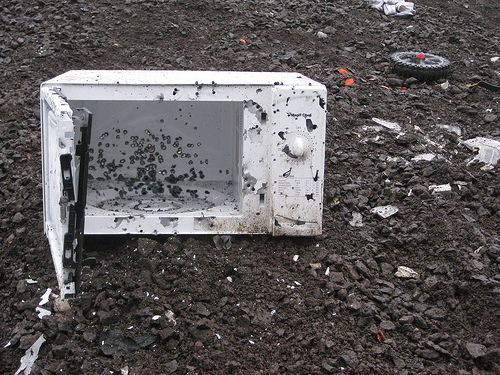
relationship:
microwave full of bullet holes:
[20, 55, 350, 311] [98, 123, 201, 208]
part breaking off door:
[75, 100, 122, 272] [28, 84, 96, 304]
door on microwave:
[39, 87, 92, 302] [40, 63, 324, 240]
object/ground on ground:
[389, 51, 449, 81] [2, 9, 496, 373]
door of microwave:
[37, 87, 92, 303] [39, 68, 329, 305]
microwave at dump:
[39, 68, 329, 305] [16, 0, 494, 372]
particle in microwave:
[143, 150, 150, 157] [39, 68, 329, 305]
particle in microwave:
[98, 130, 109, 140] [39, 68, 329, 305]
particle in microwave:
[159, 132, 171, 144] [39, 68, 329, 305]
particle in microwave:
[145, 141, 151, 150] [39, 68, 329, 305]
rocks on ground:
[155, 287, 307, 363] [2, 9, 496, 373]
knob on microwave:
[282, 127, 317, 166] [39, 68, 329, 305]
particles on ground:
[345, 108, 475, 218] [2, 9, 496, 373]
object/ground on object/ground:
[389, 39, 449, 81] [37, 67, 326, 287]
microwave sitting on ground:
[39, 68, 329, 305] [2, 9, 496, 373]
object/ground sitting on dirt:
[389, 51, 449, 81] [3, 2, 499, 372]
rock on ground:
[393, 265, 417, 281] [2, 9, 496, 373]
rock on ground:
[379, 318, 397, 330] [2, 9, 496, 373]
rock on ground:
[424, 307, 445, 318] [2, 9, 496, 373]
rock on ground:
[426, 331, 450, 340] [2, 9, 496, 373]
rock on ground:
[354, 258, 371, 274] [2, 9, 496, 373]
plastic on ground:
[35, 68, 330, 302] [2, 9, 496, 373]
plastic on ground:
[464, 136, 499, 166] [2, 9, 496, 373]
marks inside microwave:
[186, 103, 197, 110] [39, 68, 329, 305]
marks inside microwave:
[191, 124, 199, 131] [39, 68, 329, 305]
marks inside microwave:
[192, 126, 199, 133] [39, 68, 329, 305]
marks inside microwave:
[175, 107, 182, 113] [39, 68, 329, 305]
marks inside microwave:
[156, 116, 166, 123] [39, 68, 329, 305]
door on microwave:
[37, 87, 92, 303] [39, 68, 329, 305]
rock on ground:
[357, 112, 424, 144] [2, 9, 496, 373]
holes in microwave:
[85, 102, 234, 192] [39, 68, 329, 305]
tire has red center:
[388, 31, 469, 93] [413, 48, 425, 62]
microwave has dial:
[39, 68, 329, 305] [78, 122, 241, 224]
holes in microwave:
[106, 126, 204, 193] [39, 68, 329, 305]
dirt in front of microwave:
[3, 2, 499, 372] [17, 51, 331, 300]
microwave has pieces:
[39, 68, 329, 305] [350, 116, 498, 283]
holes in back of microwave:
[82, 103, 219, 207] [39, 68, 329, 305]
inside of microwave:
[66, 103, 241, 210] [39, 68, 329, 305]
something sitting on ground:
[397, 85, 408, 92] [2, 9, 496, 373]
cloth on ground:
[371, 0, 417, 17] [194, 260, 461, 350]